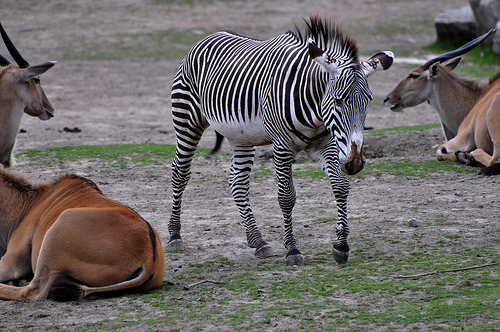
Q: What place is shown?
A: It is a field.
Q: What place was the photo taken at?
A: It was taken at the field.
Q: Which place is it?
A: It is a field.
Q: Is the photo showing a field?
A: Yes, it is showing a field.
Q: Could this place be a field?
A: Yes, it is a field.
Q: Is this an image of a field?
A: Yes, it is showing a field.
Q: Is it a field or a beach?
A: It is a field.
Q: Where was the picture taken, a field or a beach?
A: It was taken at a field.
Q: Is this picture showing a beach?
A: No, the picture is showing a field.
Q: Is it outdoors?
A: Yes, it is outdoors.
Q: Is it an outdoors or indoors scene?
A: It is outdoors.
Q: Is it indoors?
A: No, it is outdoors.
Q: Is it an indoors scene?
A: No, it is outdoors.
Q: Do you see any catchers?
A: No, there are no catchers.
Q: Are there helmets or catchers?
A: No, there are no catchers or helmets.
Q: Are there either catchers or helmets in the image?
A: No, there are no catchers or helmets.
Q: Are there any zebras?
A: Yes, there is a zebra.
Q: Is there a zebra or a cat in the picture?
A: Yes, there is a zebra.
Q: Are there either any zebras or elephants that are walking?
A: Yes, the zebra is walking.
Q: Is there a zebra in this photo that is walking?
A: Yes, there is a zebra that is walking.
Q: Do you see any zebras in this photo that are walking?
A: Yes, there is a zebra that is walking.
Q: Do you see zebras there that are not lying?
A: Yes, there is a zebra that is walking .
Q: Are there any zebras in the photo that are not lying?
A: Yes, there is a zebra that is walking.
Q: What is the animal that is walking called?
A: The animal is a zebra.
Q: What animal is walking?
A: The animal is a zebra.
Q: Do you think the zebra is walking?
A: Yes, the zebra is walking.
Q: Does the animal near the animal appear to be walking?
A: Yes, the zebra is walking.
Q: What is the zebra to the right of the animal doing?
A: The zebra is walking.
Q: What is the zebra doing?
A: The zebra is walking.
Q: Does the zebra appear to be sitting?
A: No, the zebra is walking.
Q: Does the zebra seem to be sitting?
A: No, the zebra is walking.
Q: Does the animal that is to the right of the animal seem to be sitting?
A: No, the zebra is walking.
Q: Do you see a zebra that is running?
A: No, there is a zebra but it is walking.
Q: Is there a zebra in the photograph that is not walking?
A: No, there is a zebra but it is walking.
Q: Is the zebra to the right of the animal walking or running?
A: The zebra is walking.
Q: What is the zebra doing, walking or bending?
A: The zebra is walking.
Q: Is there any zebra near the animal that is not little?
A: Yes, there is a zebra near the animal.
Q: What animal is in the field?
A: The zebra is in the field.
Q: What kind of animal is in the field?
A: The animal is a zebra.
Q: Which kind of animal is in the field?
A: The animal is a zebra.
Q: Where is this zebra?
A: The zebra is in the field.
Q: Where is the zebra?
A: The zebra is in the field.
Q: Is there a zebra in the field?
A: Yes, there is a zebra in the field.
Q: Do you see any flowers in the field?
A: No, there is a zebra in the field.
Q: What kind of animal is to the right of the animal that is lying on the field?
A: The animal is a zebra.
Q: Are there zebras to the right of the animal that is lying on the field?
A: Yes, there is a zebra to the right of the animal.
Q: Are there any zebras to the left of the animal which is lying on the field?
A: No, the zebra is to the right of the animal.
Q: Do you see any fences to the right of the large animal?
A: No, there is a zebra to the right of the animal.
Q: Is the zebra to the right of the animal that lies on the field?
A: Yes, the zebra is to the right of the animal.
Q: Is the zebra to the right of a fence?
A: No, the zebra is to the right of an animal.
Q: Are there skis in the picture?
A: No, there are no skis.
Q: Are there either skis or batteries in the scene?
A: No, there are no skis or batteries.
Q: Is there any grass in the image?
A: Yes, there is grass.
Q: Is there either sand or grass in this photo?
A: Yes, there is grass.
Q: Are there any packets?
A: No, there are no packets.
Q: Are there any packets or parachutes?
A: No, there are no packets or parachutes.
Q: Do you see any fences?
A: No, there are no fences.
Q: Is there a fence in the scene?
A: No, there are no fences.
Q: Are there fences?
A: No, there are no fences.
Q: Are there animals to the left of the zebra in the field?
A: Yes, there is an animal to the left of the zebra.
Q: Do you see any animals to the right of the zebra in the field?
A: No, the animal is to the left of the zebra.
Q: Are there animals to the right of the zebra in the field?
A: No, the animal is to the left of the zebra.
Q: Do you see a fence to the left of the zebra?
A: No, there is an animal to the left of the zebra.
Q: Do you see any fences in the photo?
A: No, there are no fences.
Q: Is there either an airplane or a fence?
A: No, there are no fences or airplanes.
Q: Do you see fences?
A: No, there are no fences.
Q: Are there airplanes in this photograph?
A: No, there are no airplanes.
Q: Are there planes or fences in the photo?
A: No, there are no planes or fences.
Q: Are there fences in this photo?
A: No, there are no fences.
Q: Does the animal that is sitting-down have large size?
A: Yes, the animal is large.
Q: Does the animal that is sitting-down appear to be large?
A: Yes, the animal is large.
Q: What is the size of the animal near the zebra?
A: The animal is large.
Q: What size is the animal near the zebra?
A: The animal is large.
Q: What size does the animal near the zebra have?
A: The animal has large size.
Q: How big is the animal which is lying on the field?
A: The animal is large.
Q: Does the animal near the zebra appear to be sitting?
A: Yes, the animal is sitting.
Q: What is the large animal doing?
A: The animal is sitting.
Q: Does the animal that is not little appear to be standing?
A: No, the animal is sitting.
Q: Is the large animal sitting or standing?
A: The animal is sitting.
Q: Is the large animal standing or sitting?
A: The animal is sitting.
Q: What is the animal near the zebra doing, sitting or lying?
A: The animal is sitting.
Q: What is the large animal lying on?
A: The animal is lying on the field.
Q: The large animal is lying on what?
A: The animal is lying on the field.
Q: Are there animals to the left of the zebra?
A: Yes, there is an animal to the left of the zebra.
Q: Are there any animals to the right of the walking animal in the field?
A: No, the animal is to the left of the zebra.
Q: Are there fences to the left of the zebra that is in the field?
A: No, there is an animal to the left of the zebra.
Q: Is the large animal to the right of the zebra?
A: No, the animal is to the left of the zebra.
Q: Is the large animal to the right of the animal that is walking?
A: No, the animal is to the left of the zebra.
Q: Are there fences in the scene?
A: No, there are no fences.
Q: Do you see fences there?
A: No, there are no fences.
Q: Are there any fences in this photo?
A: No, there are no fences.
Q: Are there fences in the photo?
A: No, there are no fences.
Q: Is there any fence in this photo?
A: No, there are no fences.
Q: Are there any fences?
A: No, there are no fences.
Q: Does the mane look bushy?
A: Yes, the mane is bushy.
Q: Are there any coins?
A: No, there are no coins.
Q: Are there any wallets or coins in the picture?
A: No, there are no coins or wallets.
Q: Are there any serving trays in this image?
A: No, there are no serving trays.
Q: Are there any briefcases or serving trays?
A: No, there are no serving trays or briefcases.